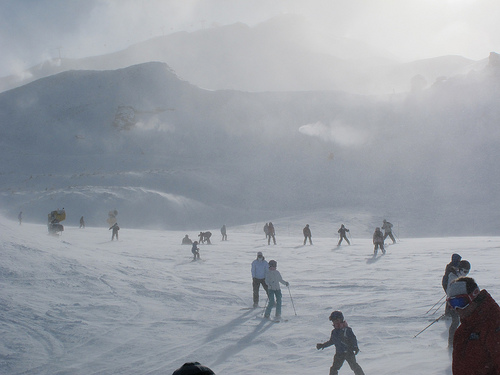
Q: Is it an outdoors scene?
A: Yes, it is outdoors.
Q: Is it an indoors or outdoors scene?
A: It is outdoors.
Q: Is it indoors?
A: No, it is outdoors.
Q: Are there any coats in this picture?
A: Yes, there is a coat.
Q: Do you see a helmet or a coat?
A: Yes, there is a coat.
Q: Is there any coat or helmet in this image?
A: Yes, there is a coat.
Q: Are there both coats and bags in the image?
A: No, there is a coat but no bags.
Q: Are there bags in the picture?
A: No, there are no bags.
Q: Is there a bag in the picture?
A: No, there are no bags.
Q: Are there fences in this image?
A: No, there are no fences.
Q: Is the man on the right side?
A: Yes, the man is on the right of the image.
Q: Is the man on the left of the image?
A: No, the man is on the right of the image.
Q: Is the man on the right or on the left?
A: The man is on the right of the image.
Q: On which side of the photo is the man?
A: The man is on the right of the image.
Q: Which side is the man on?
A: The man is on the right of the image.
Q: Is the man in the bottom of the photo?
A: Yes, the man is in the bottom of the image.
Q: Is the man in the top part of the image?
A: No, the man is in the bottom of the image.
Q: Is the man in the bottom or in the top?
A: The man is in the bottom of the image.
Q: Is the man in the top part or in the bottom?
A: The man is in the bottom of the image.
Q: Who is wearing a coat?
A: The man is wearing a coat.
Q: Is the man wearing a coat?
A: Yes, the man is wearing a coat.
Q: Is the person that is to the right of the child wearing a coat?
A: Yes, the man is wearing a coat.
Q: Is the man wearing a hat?
A: No, the man is wearing a coat.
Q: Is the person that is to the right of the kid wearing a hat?
A: No, the man is wearing a coat.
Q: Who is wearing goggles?
A: The man is wearing goggles.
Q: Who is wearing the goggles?
A: The man is wearing goggles.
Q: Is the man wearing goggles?
A: Yes, the man is wearing goggles.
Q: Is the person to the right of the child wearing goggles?
A: Yes, the man is wearing goggles.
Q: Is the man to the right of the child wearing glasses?
A: No, the man is wearing goggles.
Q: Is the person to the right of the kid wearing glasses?
A: No, the man is wearing goggles.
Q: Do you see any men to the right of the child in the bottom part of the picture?
A: Yes, there is a man to the right of the child.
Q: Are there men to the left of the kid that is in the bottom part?
A: No, the man is to the right of the kid.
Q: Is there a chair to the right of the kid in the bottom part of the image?
A: No, there is a man to the right of the child.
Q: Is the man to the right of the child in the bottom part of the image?
A: Yes, the man is to the right of the child.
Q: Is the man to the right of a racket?
A: No, the man is to the right of the child.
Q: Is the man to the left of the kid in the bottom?
A: No, the man is to the right of the kid.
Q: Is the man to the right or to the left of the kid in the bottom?
A: The man is to the right of the child.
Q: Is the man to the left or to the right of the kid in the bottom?
A: The man is to the right of the child.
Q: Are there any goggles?
A: Yes, there are goggles.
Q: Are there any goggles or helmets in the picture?
A: Yes, there are goggles.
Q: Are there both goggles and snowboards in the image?
A: No, there are goggles but no snowboards.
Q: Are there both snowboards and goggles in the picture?
A: No, there are goggles but no snowboards.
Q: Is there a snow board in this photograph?
A: No, there are no snowboards.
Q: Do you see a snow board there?
A: No, there are no snowboards.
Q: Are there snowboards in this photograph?
A: No, there are no snowboards.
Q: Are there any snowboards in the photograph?
A: No, there are no snowboards.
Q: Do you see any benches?
A: No, there are no benches.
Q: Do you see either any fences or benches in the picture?
A: No, there are no benches or fences.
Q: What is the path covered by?
A: The path is covered by the snow.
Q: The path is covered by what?
A: The path is covered by the snow.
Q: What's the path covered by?
A: The path is covered by the snow.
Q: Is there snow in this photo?
A: Yes, there is snow.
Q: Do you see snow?
A: Yes, there is snow.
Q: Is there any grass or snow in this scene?
A: Yes, there is snow.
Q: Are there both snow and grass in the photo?
A: No, there is snow but no grass.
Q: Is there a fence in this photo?
A: No, there are no fences.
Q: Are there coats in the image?
A: Yes, there is a coat.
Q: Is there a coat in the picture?
A: Yes, there is a coat.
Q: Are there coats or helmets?
A: Yes, there is a coat.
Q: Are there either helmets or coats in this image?
A: Yes, there is a coat.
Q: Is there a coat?
A: Yes, there is a coat.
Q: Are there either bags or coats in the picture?
A: Yes, there is a coat.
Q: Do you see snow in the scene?
A: Yes, there is snow.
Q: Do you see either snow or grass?
A: Yes, there is snow.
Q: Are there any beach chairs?
A: No, there are no beach chairs.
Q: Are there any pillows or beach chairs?
A: No, there are no beach chairs or pillows.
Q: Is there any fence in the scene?
A: No, there are no fences.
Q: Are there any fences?
A: No, there are no fences.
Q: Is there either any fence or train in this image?
A: No, there are no fences or trains.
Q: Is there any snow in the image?
A: Yes, there is snow.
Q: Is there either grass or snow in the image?
A: Yes, there is snow.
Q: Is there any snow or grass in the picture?
A: Yes, there is snow.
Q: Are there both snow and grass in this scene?
A: No, there is snow but no grass.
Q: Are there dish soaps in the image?
A: No, there are no dish soaps.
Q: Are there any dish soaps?
A: No, there are no dish soaps.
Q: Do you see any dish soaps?
A: No, there are no dish soaps.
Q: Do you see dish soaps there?
A: No, there are no dish soaps.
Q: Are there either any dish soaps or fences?
A: No, there are no dish soaps or fences.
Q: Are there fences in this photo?
A: No, there are no fences.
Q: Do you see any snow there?
A: Yes, there is snow.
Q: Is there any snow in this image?
A: Yes, there is snow.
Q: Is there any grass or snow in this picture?
A: Yes, there is snow.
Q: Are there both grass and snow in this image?
A: No, there is snow but no grass.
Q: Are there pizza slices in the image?
A: No, there are no pizza slices.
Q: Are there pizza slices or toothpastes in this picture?
A: No, there are no pizza slices or toothpastes.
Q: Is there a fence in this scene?
A: No, there are no fences.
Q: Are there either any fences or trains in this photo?
A: No, there are no fences or trains.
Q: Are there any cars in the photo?
A: No, there are no cars.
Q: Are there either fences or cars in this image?
A: No, there are no cars or fences.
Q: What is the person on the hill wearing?
A: The person is wearing a coat.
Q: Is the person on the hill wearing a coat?
A: Yes, the person is wearing a coat.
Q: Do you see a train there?
A: No, there are no trains.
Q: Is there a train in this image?
A: No, there are no trains.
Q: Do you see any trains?
A: No, there are no trains.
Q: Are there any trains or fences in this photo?
A: No, there are no trains or fences.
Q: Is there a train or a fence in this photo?
A: No, there are no trains or fences.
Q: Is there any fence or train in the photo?
A: No, there are no trains or fences.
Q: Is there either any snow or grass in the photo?
A: Yes, there is snow.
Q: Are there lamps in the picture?
A: No, there are no lamps.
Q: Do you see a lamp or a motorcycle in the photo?
A: No, there are no lamps or motorcycles.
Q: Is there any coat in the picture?
A: Yes, there is a coat.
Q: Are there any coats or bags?
A: Yes, there is a coat.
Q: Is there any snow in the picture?
A: Yes, there is snow.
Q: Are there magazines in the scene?
A: No, there are no magazines.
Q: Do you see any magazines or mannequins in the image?
A: No, there are no magazines or mannequins.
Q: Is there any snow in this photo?
A: Yes, there is snow.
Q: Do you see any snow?
A: Yes, there is snow.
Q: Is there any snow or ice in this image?
A: Yes, there is snow.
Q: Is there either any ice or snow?
A: Yes, there is snow.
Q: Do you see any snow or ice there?
A: Yes, there is snow.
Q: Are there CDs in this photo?
A: No, there are no cds.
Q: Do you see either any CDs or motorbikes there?
A: No, there are no CDs or motorbikes.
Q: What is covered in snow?
A: The mountains are covered in snow.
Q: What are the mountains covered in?
A: The mountains are covered in snow.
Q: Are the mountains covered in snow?
A: Yes, the mountains are covered in snow.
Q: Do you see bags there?
A: No, there are no bags.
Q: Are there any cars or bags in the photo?
A: No, there are no bags or cars.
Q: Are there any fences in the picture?
A: No, there are no fences.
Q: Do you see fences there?
A: No, there are no fences.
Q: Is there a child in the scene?
A: Yes, there is a child.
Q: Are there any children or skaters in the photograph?
A: Yes, there is a child.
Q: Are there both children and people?
A: Yes, there are both a child and people.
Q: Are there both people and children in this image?
A: Yes, there are both a child and people.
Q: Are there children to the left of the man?
A: Yes, there is a child to the left of the man.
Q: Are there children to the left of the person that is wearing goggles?
A: Yes, there is a child to the left of the man.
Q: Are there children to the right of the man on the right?
A: No, the child is to the left of the man.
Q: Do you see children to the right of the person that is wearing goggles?
A: No, the child is to the left of the man.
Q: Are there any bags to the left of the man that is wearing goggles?
A: No, there is a child to the left of the man.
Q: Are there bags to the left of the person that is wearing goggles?
A: No, there is a child to the left of the man.